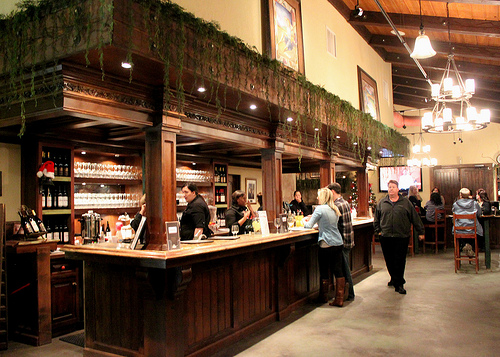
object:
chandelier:
[420, 100, 491, 134]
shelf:
[73, 177, 143, 185]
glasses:
[134, 166, 140, 179]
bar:
[0, 0, 411, 355]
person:
[453, 185, 484, 265]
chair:
[453, 212, 478, 274]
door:
[431, 164, 494, 203]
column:
[144, 126, 177, 250]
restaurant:
[0, 0, 499, 357]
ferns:
[17, 5, 26, 137]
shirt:
[373, 193, 425, 238]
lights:
[424, 112, 434, 125]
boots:
[329, 277, 345, 307]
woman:
[304, 186, 354, 307]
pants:
[309, 244, 355, 294]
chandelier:
[428, 54, 476, 102]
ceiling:
[335, 5, 500, 124]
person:
[328, 179, 357, 304]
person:
[371, 171, 437, 271]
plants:
[393, 129, 399, 168]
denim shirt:
[304, 204, 345, 247]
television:
[380, 165, 421, 190]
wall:
[371, 106, 498, 248]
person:
[451, 184, 483, 256]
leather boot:
[308, 279, 329, 303]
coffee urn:
[78, 210, 103, 245]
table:
[445, 215, 500, 268]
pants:
[379, 233, 410, 286]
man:
[373, 180, 427, 294]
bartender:
[178, 183, 214, 241]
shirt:
[180, 195, 214, 241]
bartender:
[129, 193, 147, 243]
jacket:
[373, 194, 425, 238]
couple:
[452, 188, 492, 256]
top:
[451, 199, 484, 237]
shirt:
[334, 197, 355, 249]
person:
[178, 183, 214, 237]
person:
[450, 180, 484, 260]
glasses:
[126, 193, 129, 207]